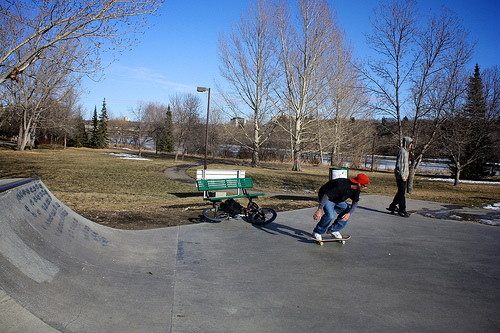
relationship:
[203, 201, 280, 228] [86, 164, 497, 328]
bicycle on ground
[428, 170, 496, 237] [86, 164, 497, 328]
snow on ground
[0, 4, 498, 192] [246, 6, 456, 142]
trees with no leaves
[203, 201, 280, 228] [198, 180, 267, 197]
bike near bench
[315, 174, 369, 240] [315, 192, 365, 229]
man has hands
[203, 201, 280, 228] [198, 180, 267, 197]
bicycle near bench